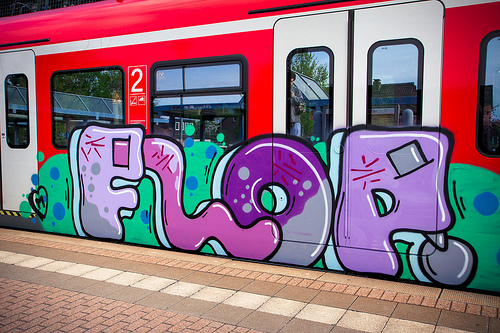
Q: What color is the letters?
A: Purple.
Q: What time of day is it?
A: Daytime.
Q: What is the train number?
A: 2.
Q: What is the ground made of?
A: Bricks and tile.